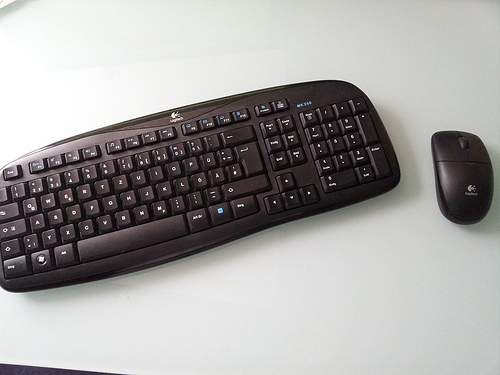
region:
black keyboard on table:
[21, 77, 382, 335]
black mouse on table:
[390, 97, 483, 260]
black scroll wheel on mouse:
[460, 130, 466, 150]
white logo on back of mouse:
[455, 173, 475, 220]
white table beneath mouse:
[133, 210, 423, 355]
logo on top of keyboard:
[153, 96, 198, 126]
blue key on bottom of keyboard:
[191, 197, 232, 230]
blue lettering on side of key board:
[280, 96, 317, 122]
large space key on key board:
[15, 205, 186, 302]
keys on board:
[25, 98, 349, 240]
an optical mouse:
[386, 121, 462, 197]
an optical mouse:
[373, 97, 498, 195]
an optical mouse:
[338, 51, 494, 189]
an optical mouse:
[384, 93, 494, 279]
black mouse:
[411, 118, 476, 218]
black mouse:
[401, 80, 488, 250]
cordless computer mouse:
[428, 131, 492, 226]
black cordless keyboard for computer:
[1, 75, 399, 293]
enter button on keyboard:
[232, 140, 269, 176]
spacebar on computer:
[72, 215, 190, 261]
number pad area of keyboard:
[296, 97, 393, 193]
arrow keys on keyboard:
[261, 173, 325, 213]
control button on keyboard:
[0, 252, 32, 279]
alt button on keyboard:
[50, 240, 77, 270]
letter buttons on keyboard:
[22, 152, 243, 257]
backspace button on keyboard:
[222, 119, 257, 146]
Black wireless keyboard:
[1, 63, 393, 303]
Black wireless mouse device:
[424, 99, 498, 236]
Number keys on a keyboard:
[298, 97, 368, 184]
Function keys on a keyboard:
[25, 97, 253, 176]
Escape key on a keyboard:
[0, 160, 23, 185]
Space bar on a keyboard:
[72, 212, 200, 269]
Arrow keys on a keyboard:
[265, 160, 316, 221]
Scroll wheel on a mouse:
[454, 128, 473, 158]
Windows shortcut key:
[29, 247, 57, 274]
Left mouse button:
[429, 125, 462, 165]